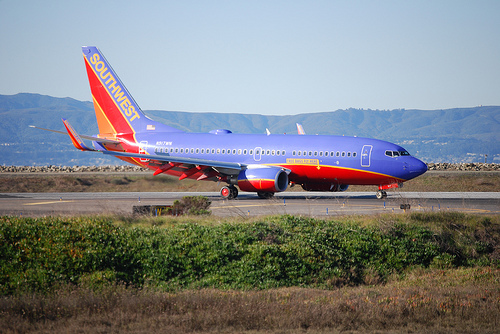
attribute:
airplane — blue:
[41, 40, 449, 213]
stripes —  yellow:
[74, 42, 169, 165]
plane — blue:
[26, 42, 426, 200]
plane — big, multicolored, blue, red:
[51, 30, 455, 209]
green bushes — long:
[8, 212, 494, 270]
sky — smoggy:
[1, 4, 499, 125]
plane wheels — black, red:
[372, 187, 391, 203]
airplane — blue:
[53, 43, 430, 216]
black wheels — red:
[371, 188, 392, 199]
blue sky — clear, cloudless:
[6, 3, 498, 112]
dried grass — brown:
[1, 285, 492, 320]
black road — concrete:
[6, 189, 499, 219]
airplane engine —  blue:
[232, 167, 287, 199]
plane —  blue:
[88, 50, 430, 176]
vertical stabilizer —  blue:
[75, 42, 150, 133]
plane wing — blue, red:
[61, 123, 242, 179]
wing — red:
[56, 117, 89, 146]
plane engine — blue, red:
[231, 163, 285, 196]